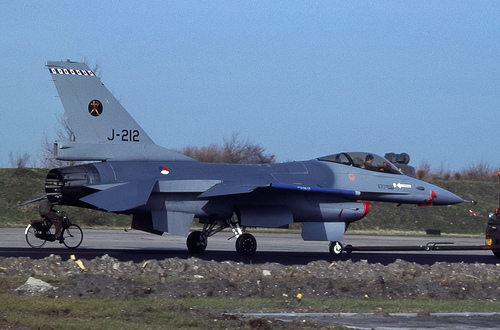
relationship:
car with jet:
[481, 201, 498, 263] [21, 51, 471, 248]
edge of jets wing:
[272, 184, 359, 196] [199, 181, 413, 207]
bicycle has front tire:
[18, 209, 85, 248] [60, 221, 84, 251]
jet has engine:
[21, 51, 471, 248] [39, 155, 99, 215]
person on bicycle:
[42, 193, 67, 247] [22, 220, 85, 247]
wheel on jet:
[328, 242, 343, 258] [21, 51, 471, 248]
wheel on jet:
[186, 230, 208, 255] [21, 51, 471, 248]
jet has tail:
[21, 51, 471, 248] [44, 57, 199, 162]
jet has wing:
[21, 51, 471, 248] [197, 175, 254, 195]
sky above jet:
[1, 0, 499, 178] [20, 61, 481, 276]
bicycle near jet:
[18, 209, 85, 248] [12, 63, 430, 278]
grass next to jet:
[50, 303, 175, 315] [21, 51, 471, 248]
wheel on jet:
[186, 230, 208, 255] [20, 61, 481, 276]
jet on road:
[21, 51, 471, 248] [0, 227, 492, 257]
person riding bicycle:
[42, 193, 67, 225] [18, 209, 85, 248]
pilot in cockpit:
[363, 152, 377, 167] [322, 150, 405, 171]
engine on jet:
[49, 162, 100, 208] [21, 51, 471, 248]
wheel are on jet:
[186, 230, 208, 255] [84, 74, 428, 281]